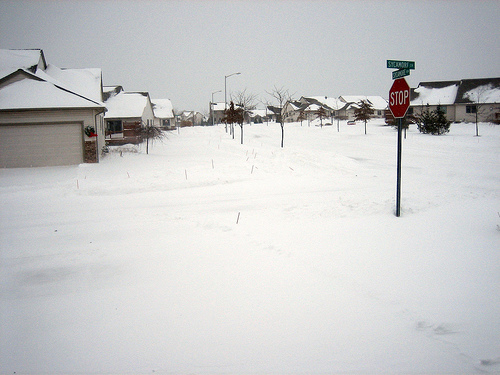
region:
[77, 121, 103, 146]
winter wreath on side of house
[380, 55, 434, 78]
green and white street sign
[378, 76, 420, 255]
red stop sign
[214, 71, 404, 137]
snow on roof tops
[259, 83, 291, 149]
tree without leaves in the winter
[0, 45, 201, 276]
yard covered in snow in the winter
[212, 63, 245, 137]
city street light pole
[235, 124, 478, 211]
snow covered street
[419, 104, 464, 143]
evergreen bush with leaves in the winter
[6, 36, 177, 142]
houses with snow covered roofs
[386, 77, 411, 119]
a red stop sign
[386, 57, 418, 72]
a green street sign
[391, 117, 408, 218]
a stop sign pole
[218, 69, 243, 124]
a gray street light pole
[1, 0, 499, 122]
a gray sky over the snow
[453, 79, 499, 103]
a black roof with snow on it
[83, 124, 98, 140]
a green and red wreath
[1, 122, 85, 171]
a garage door of a house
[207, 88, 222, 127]
a gray street light post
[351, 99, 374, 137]
a small green tree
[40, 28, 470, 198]
residential area covered in snow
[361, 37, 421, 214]
stop sign and street signs on one pole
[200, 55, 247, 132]
lampposts rising out of snow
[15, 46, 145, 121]
snow covering different angled roofs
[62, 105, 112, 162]
Christmas wreath on side of garage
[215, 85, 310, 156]
short trees with leafless branches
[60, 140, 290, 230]
sticks poking out of the snow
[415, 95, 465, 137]
two evergreen trees next to each other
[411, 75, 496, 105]
roofs partially covered in snow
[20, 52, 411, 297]
road covered in snow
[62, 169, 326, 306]
snow covered ground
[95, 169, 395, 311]
White snow covering the street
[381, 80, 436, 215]
Red stop sign on a pole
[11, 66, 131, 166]
House covered with snow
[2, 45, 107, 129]
White snow on a roof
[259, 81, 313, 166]
Brown tree standing in snow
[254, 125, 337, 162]
Snow on the ground around a tree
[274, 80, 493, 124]
Several houses with snow on them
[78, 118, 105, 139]
Wreath hanging on a tan house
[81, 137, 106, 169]
Brown brick on a tan house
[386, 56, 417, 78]
street signs atop the stop sign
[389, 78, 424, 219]
stop sign on the corner of street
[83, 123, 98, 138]
wreath affixed to the garage of house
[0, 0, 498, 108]
the sky is clear of clouds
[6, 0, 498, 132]
sky is light gray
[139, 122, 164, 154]
small tree in front of the house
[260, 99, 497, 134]
leafless trees a lining the curbside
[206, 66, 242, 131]
street lights a lining the curbside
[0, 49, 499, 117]
roofs of houses covered with snow